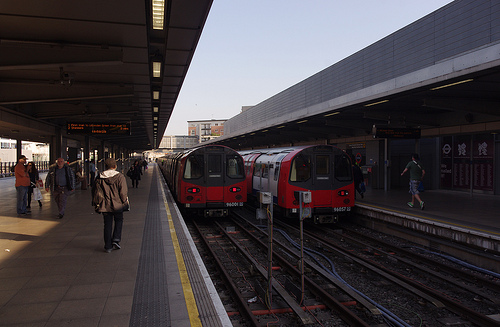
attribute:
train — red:
[155, 148, 245, 216]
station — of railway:
[204, 10, 498, 255]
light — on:
[228, 182, 245, 191]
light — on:
[185, 181, 199, 194]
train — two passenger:
[154, 142, 249, 220]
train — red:
[147, 144, 248, 219]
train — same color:
[161, 137, 251, 209]